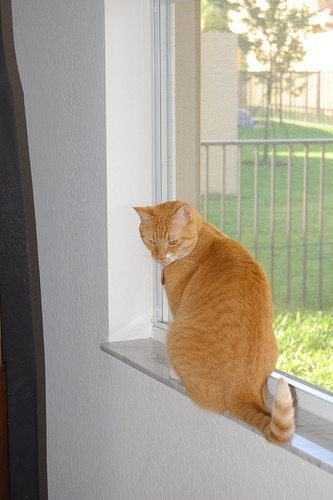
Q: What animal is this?
A: A cat.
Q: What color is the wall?
A: White.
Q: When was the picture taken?
A: Daytime.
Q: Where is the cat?
A: On the ledge.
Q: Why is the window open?
A: To let the light in.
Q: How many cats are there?
A: One.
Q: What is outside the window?
A: A fence.